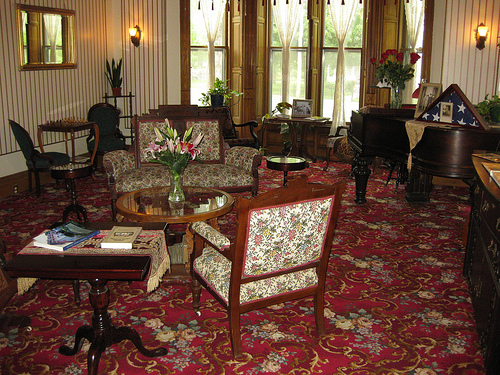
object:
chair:
[185, 181, 347, 360]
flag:
[418, 88, 486, 130]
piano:
[345, 107, 500, 205]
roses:
[369, 48, 422, 109]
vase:
[390, 86, 403, 109]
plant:
[197, 77, 244, 107]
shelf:
[102, 92, 136, 145]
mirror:
[20, 9, 64, 64]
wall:
[4, 13, 93, 117]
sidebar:
[33, 115, 88, 148]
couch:
[103, 104, 263, 222]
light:
[127, 25, 141, 48]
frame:
[19, 63, 78, 71]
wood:
[0, 222, 170, 374]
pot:
[111, 87, 122, 96]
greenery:
[104, 57, 123, 88]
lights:
[475, 22, 489, 51]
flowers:
[141, 117, 205, 202]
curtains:
[222, 0, 270, 138]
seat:
[85, 102, 126, 171]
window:
[189, 0, 363, 122]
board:
[115, 186, 234, 225]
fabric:
[190, 163, 229, 181]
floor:
[368, 240, 450, 337]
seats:
[5, 117, 71, 200]